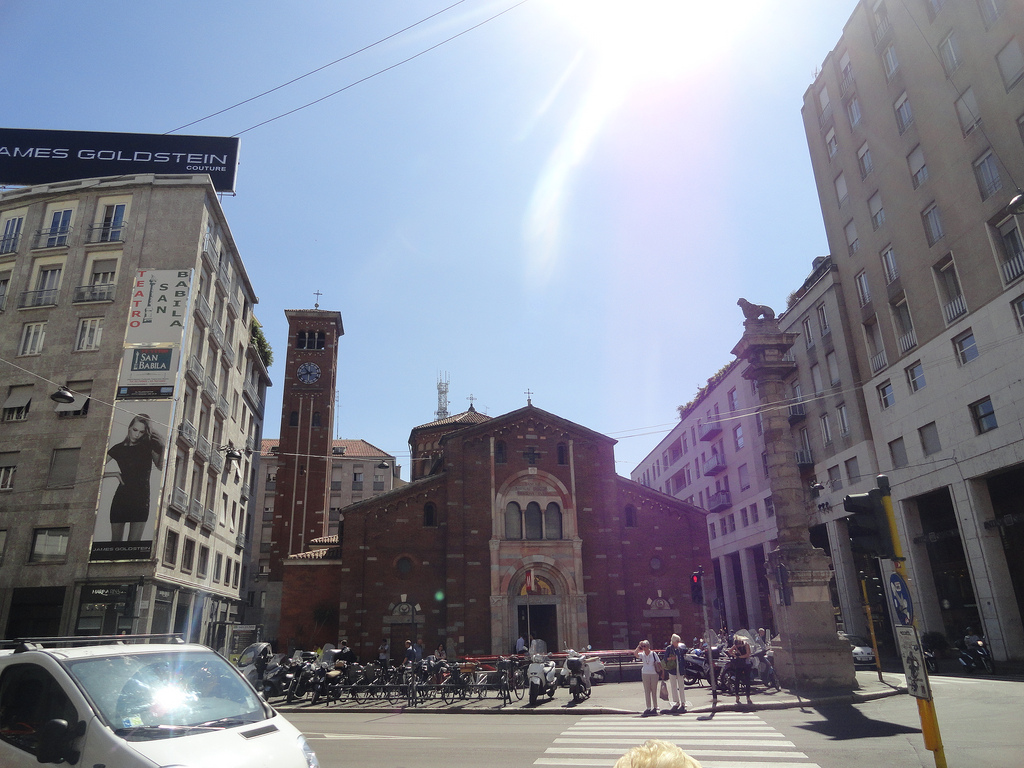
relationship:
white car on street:
[2, 640, 320, 767] [294, 680, 1021, 766]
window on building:
[869, 370, 914, 415] [799, 1, 1021, 669]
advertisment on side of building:
[70, 263, 203, 564] [0, 169, 242, 640]